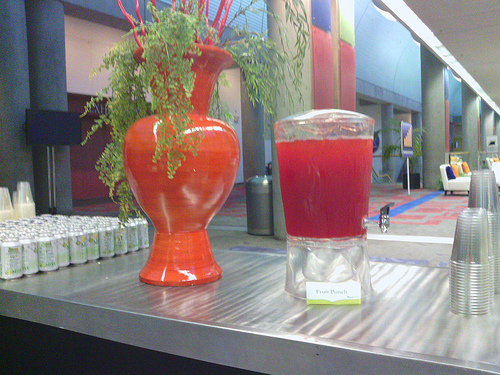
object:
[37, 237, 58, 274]
soda cans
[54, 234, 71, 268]
soda cans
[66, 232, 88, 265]
soda cans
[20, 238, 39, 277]
soda cans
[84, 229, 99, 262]
soda cans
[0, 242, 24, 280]
cans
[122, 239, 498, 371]
counter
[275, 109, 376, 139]
glass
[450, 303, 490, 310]
plastic cups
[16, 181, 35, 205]
plastic cups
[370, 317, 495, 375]
table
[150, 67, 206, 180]
leaves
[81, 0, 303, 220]
plant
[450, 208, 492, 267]
cup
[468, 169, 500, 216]
cup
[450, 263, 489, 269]
cup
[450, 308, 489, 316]
cup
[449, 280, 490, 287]
cup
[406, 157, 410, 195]
pole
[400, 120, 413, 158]
sign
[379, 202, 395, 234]
spout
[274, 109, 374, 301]
container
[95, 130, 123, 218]
greenery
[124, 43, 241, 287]
vase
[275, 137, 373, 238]
drink